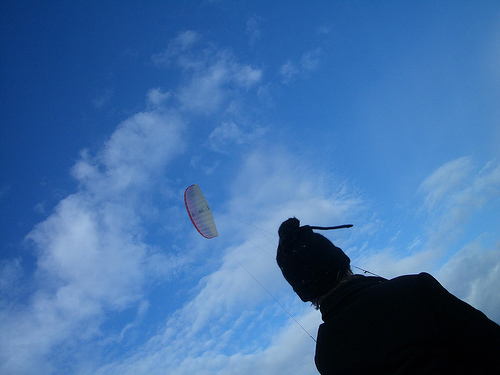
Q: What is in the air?
A: Kite.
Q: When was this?
A: Daytime.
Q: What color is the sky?
A: Blue.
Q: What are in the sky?
A: Clouds.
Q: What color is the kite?
A: White.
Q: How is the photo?
A: Clear.